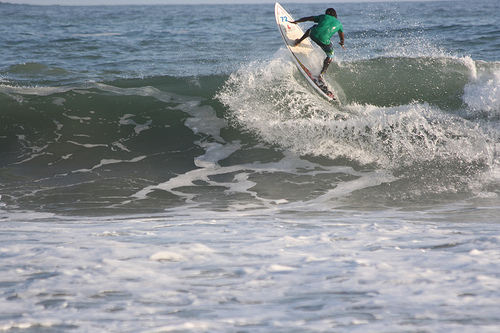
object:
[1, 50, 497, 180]
wave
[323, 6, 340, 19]
head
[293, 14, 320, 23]
arm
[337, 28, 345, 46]
arm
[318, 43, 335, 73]
leg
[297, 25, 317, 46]
leg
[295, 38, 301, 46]
foot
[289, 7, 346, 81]
body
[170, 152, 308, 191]
water foam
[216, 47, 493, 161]
wake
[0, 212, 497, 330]
water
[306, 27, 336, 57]
shorts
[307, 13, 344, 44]
t-shirt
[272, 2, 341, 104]
board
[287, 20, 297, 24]
hand